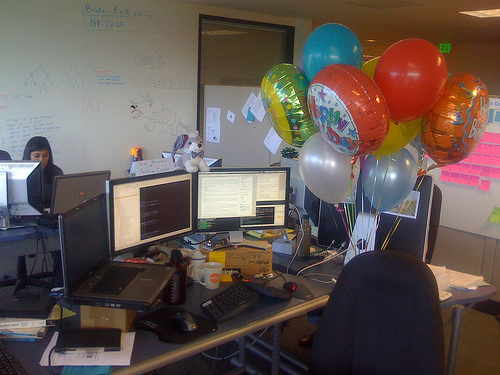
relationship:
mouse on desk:
[172, 309, 199, 333] [0, 234, 351, 374]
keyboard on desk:
[202, 280, 261, 327] [0, 234, 351, 374]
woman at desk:
[23, 135, 66, 215] [0, 197, 94, 260]